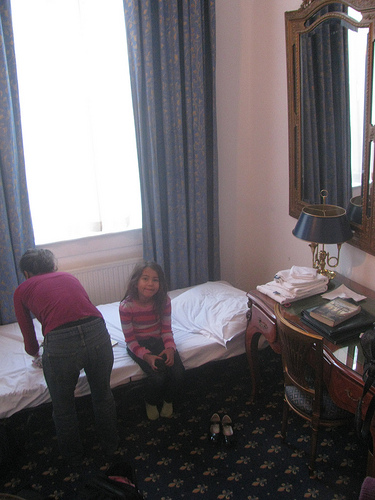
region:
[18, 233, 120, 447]
this is a lady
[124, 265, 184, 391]
this is a girl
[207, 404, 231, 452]
this is a pair of shoe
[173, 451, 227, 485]
this is the floor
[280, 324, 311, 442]
this is a chair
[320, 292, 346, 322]
this is a book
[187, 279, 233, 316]
this is a pillow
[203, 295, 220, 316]
the pillow is white in color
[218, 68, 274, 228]
this is a wall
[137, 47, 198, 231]
this is a curtain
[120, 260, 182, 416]
Young girl sitting on white bed sheets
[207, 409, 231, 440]
Black polished shoes sitting on floor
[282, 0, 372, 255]
Large wooden mirror hanging on wall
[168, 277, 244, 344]
White pillow sitting on bed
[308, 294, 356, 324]
Book laying on a desk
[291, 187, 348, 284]
Blue and gold desk lamp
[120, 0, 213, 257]
Large blue and yellow curtains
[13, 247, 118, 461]
Woman bending over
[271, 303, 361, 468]
Elegant wooden desk chair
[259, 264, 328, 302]
White cloth bath towels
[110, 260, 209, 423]
A young girl in a striped shirt sitting on a bed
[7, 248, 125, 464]
a woman in a pink shirt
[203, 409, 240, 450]
a pair of shoes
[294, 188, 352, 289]
a lamp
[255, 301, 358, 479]
a chair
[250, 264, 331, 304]
a set of bed sheets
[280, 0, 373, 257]
a wall mirror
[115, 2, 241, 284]
wall to ceiling curtains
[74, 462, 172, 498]
a bag on the floor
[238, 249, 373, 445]
an ornate table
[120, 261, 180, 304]
the girl is looking at camera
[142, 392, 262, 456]
the girl's shoes are off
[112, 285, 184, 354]
the girl's shirt is striped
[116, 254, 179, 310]
the girl's hair is brown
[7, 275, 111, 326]
the woman's shirt is pink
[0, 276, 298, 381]
the sheets on bed are white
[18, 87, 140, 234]
the light is shining through window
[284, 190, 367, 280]
the lamp shade is green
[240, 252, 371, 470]
the desk is made of wood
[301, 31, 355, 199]
the curtain is reflecting into mirror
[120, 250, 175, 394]
this is a small girl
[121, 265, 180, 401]
the girl is sitted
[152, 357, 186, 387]
the knees are bent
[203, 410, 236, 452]
the shoes are on the floor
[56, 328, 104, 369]
the butt are behind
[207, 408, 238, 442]
the shoes are black in color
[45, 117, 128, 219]
the window is closed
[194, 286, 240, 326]
this is a pillow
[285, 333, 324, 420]
the chair is wooden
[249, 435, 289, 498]
the mat is black in color